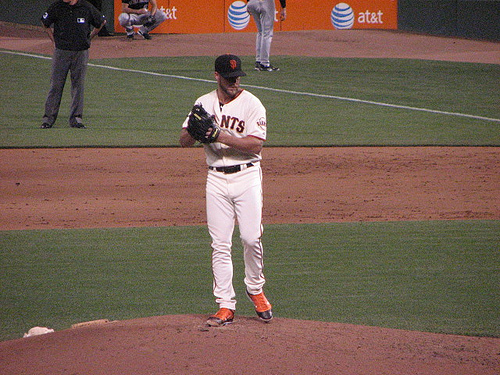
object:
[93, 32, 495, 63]
dirt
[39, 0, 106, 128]
umpire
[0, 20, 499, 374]
field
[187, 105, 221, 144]
glove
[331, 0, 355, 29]
logo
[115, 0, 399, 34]
advertisement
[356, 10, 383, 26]
at&t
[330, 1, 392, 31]
light post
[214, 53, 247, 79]
cap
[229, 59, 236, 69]
logo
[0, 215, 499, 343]
grass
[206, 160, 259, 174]
belt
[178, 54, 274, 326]
pitcher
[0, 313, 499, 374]
mound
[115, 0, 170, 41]
player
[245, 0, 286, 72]
player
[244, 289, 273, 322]
shoe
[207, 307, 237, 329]
shoe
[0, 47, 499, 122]
line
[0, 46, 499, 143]
grass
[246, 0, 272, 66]
pants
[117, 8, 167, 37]
pants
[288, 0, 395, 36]
wall